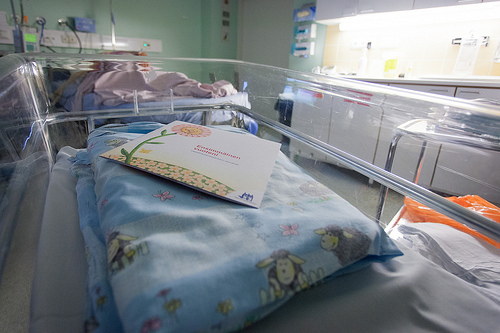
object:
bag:
[403, 194, 499, 248]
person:
[45, 53, 267, 125]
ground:
[280, 136, 407, 226]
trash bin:
[268, 85, 301, 143]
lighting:
[322, 2, 497, 42]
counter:
[314, 74, 499, 90]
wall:
[8, 5, 236, 115]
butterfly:
[279, 222, 304, 239]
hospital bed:
[50, 71, 260, 146]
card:
[98, 120, 283, 209]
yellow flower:
[118, 115, 211, 170]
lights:
[315, 4, 496, 90]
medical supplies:
[3, 0, 163, 57]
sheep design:
[235, 217, 397, 314]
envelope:
[121, 120, 267, 205]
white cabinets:
[285, 65, 499, 204]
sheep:
[250, 247, 313, 299]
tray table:
[375, 115, 499, 222]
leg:
[375, 132, 403, 222]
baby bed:
[1, 49, 499, 330]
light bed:
[131, 38, 234, 106]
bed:
[43, 79, 261, 140]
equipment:
[73, 17, 96, 33]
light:
[101, 35, 129, 52]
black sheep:
[311, 223, 373, 268]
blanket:
[73, 55, 240, 116]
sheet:
[76, 66, 238, 106]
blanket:
[66, 120, 404, 332]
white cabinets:
[311, 49, 498, 201]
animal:
[255, 250, 313, 298]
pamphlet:
[97, 115, 284, 214]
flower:
[171, 124, 213, 138]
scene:
[48, 26, 486, 266]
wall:
[172, 9, 197, 54]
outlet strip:
[0, 24, 164, 54]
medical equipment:
[2, 22, 166, 54]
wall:
[0, 0, 245, 105]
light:
[319, 2, 499, 44]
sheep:
[254, 248, 318, 296]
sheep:
[320, 215, 371, 271]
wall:
[0, 1, 237, 80]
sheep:
[246, 258, 301, 290]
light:
[128, 12, 189, 92]